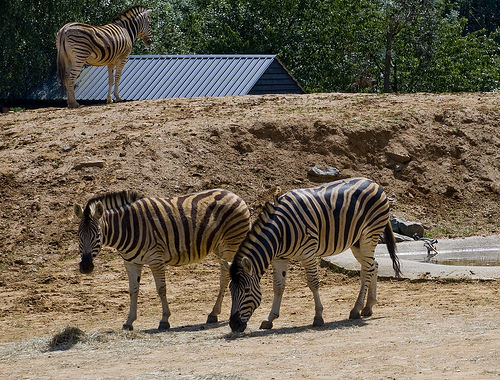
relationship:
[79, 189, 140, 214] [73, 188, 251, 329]
mane of zebra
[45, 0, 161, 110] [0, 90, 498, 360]
zebra standing on ground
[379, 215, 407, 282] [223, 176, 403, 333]
tail on zebra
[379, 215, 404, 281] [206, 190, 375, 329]
tail on zebra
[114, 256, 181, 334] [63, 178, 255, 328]
legs behind zebra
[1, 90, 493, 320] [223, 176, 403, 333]
dirt mountain behind zebra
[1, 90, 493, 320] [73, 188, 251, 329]
dirt mountain behind zebra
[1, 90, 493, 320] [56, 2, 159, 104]
dirt mountain behind zebra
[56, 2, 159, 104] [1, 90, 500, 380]
zebra on dirt mountain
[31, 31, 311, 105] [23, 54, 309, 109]
roof on building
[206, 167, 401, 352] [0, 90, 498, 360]
zebra eating from ground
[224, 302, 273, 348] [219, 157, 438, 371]
muzzle on zebra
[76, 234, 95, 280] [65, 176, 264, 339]
muzzle on zebra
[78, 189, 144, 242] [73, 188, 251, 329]
mane on zebra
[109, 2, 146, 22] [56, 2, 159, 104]
mane on zebra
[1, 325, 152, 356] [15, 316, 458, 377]
grass on ground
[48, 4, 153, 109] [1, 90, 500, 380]
zebra on dirt mountain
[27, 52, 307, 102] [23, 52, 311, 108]
roof on building